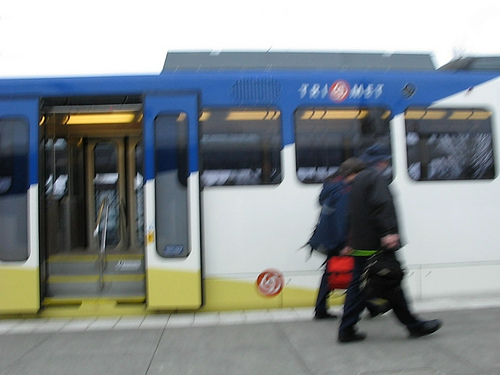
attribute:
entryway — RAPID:
[33, 310, 143, 355]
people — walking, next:
[276, 122, 412, 347]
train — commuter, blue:
[2, 45, 473, 347]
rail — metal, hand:
[88, 182, 124, 283]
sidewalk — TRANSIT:
[49, 302, 268, 375]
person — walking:
[279, 112, 422, 330]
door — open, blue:
[25, 74, 203, 361]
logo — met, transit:
[248, 259, 287, 299]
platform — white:
[41, 293, 149, 339]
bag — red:
[313, 245, 391, 292]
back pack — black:
[343, 236, 423, 305]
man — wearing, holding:
[308, 157, 443, 349]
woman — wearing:
[272, 101, 416, 333]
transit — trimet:
[9, 53, 205, 368]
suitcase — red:
[312, 251, 385, 295]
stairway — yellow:
[17, 281, 157, 334]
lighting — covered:
[23, 106, 153, 142]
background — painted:
[248, 72, 363, 111]